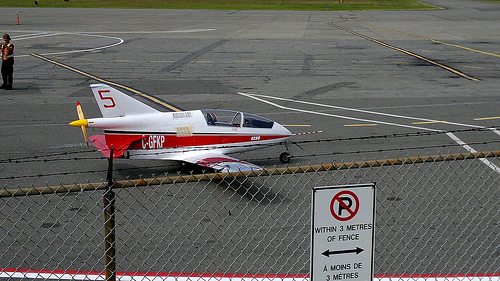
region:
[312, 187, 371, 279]
No parking sign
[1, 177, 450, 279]
Chain link fence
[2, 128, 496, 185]
Barbed Wire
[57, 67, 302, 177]
Small air plane, painted red and white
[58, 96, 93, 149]
Air plane propeller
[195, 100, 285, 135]
Air plane cockpit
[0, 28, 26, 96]
A person wearing a safety vest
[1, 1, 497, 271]
Paved air plane run way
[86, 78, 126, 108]
The number five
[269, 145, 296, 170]
A wheel, part of the landing gear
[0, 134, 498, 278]
rusty metal chain link fence with barbed wire on top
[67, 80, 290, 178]
small aerodynamic red white and yellow plane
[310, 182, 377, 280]
white no parking sign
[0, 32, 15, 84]
male standing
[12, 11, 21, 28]
bright orange safety cone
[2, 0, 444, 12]
short green grass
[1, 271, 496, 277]
red and white painted stripes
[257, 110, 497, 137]
dotted yellow painted stripe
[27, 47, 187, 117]
solid yellow and black painted line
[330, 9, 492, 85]
solid yellow and black painted line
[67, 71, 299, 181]
Small private plane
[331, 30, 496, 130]
Tarmac at airstrip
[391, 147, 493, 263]
Chain link fence around tarmac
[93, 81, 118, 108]
Number five in red on plane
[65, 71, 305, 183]
Red and white plane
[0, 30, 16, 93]
Man in safety vest working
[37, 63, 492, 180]
Plane on tarmac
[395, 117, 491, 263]
Barbed wire on fencing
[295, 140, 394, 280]
No parking sign on fencing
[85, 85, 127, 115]
Number on wing of plane.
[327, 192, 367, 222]
No Parking symbol on sign.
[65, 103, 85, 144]
Yellow spinning part of plane.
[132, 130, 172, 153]
Letters on red strip of plane.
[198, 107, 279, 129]
Window at the front of the plane.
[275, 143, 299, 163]
Wheel in the front of the plane.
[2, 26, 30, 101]
Person standing in back of plane.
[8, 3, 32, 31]
Orange cone in landing area.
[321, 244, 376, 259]
Arrow symbol on No Parking sign.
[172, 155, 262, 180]
Flat wing of plane with red stripe on it.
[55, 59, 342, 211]
A plane sits on the tarmac.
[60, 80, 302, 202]
The plane is a small aircraft.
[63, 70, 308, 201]
The plane is red and white.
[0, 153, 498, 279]
A chain link fence is in front of the tarmac.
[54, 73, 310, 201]
The plane faces right.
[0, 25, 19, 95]
A person stands on the tarmac.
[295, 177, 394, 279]
A sign is attached to the fence.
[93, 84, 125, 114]
The number 5 is on the plane's tail.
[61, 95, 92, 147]
A yellow propeller is on the back of the plane.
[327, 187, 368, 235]
The sign indicates no parking.